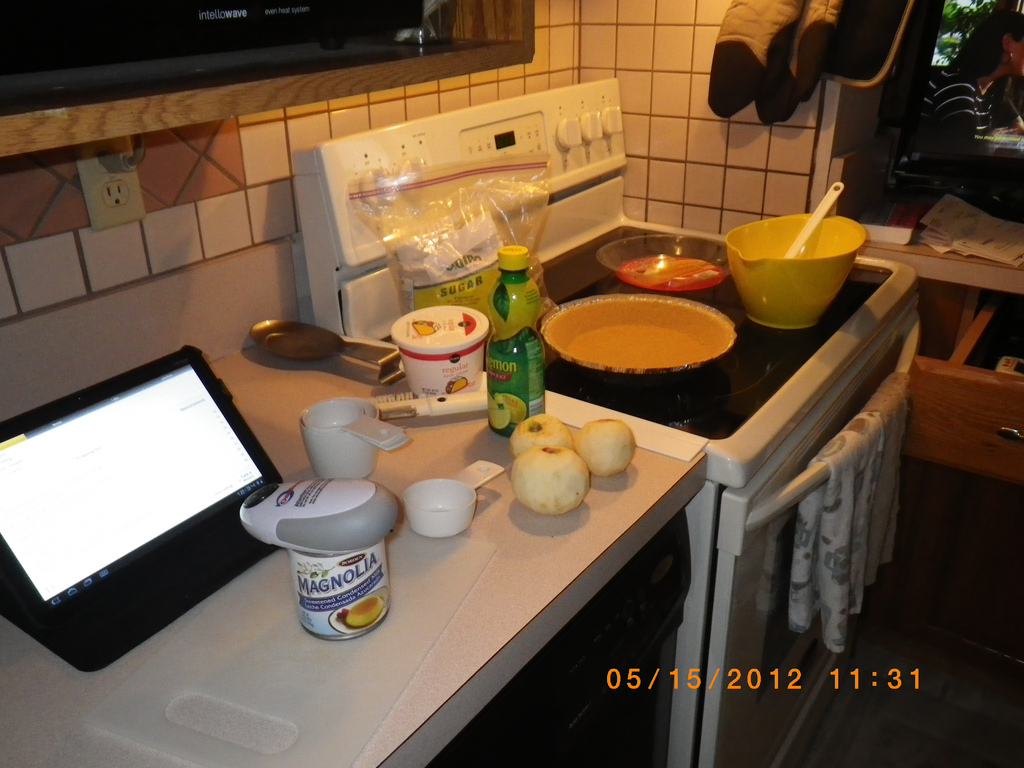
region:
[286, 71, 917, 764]
White kitchen stove with a black cooktop.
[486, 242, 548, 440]
Green and yellow bottle of lemon juice.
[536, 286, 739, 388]
Pie pan with a graham cracker pie crust.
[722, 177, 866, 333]
White spoon in a yellow mixing bowl.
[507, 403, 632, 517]
Three whole pilled apples.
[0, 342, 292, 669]
black framed recipe reader.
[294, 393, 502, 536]
Set of white measuring cups.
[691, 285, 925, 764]
Dish towel hanging on an oven door handle.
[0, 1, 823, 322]
Tan and brown wall tiles.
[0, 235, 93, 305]
a tile in a wall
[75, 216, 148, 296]
a tile in a wall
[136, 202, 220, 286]
a tile in a wall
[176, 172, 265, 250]
a tile in a wall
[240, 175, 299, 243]
a tile in a wall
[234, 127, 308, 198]
a tile in a wall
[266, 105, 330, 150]
a tile in a wall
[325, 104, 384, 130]
a tile in a wall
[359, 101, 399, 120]
a tile in a wall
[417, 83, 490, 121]
a tile in a wall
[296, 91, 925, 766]
a white and black stove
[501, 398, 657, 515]
three peeled apples on the counter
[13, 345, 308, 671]
a tablet propped up on the counter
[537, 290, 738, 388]
an empty pie crust on the stove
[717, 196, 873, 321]
a yellow mixing bowl with white handle sticking out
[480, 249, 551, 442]
a bottle of lemon juice on the counter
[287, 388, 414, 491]
two white measuring cups stacked together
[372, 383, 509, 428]
a white handled peeler on the counter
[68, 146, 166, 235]
an electrical outlet with one plug in it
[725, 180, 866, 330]
yellow mixing bowl with white handled instrument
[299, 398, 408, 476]
stacked white measuring cups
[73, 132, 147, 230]
off white electrical outlet with grey plug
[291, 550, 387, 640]
round container that says magnolia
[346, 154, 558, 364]
bag of sugar inside of clear plastic bag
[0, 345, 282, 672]
black powered on computer tablet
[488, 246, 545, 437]
green and yellow lemon juice bottle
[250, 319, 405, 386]
large empty brass spoon holder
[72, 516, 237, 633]
a view of key board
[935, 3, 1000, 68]
glass is clean and clear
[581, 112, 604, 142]
stove has a know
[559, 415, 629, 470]
onion on the counter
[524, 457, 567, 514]
an onion on the counter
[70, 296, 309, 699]
a tablet on the counter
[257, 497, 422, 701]
a can on the counter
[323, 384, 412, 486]
a measuring cup on the counter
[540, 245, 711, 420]
a plate on the table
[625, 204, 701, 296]
a bowl on the stove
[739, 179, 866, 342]
a bowl on the stove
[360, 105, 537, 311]
sugar in a bag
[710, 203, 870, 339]
yellow bowl on stove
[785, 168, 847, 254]
white mixing spoon in bowl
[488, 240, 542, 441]
green bottle of lemon juice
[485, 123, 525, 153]
digital clock on stove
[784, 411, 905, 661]
dish towel hanging from stove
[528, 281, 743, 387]
orange pie plate on stove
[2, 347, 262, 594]
screen of tablet computer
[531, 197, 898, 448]
black cook top on stove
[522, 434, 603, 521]
A piece of food.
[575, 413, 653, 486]
A piece of food.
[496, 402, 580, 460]
A piece of food.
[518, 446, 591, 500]
A piece of food.